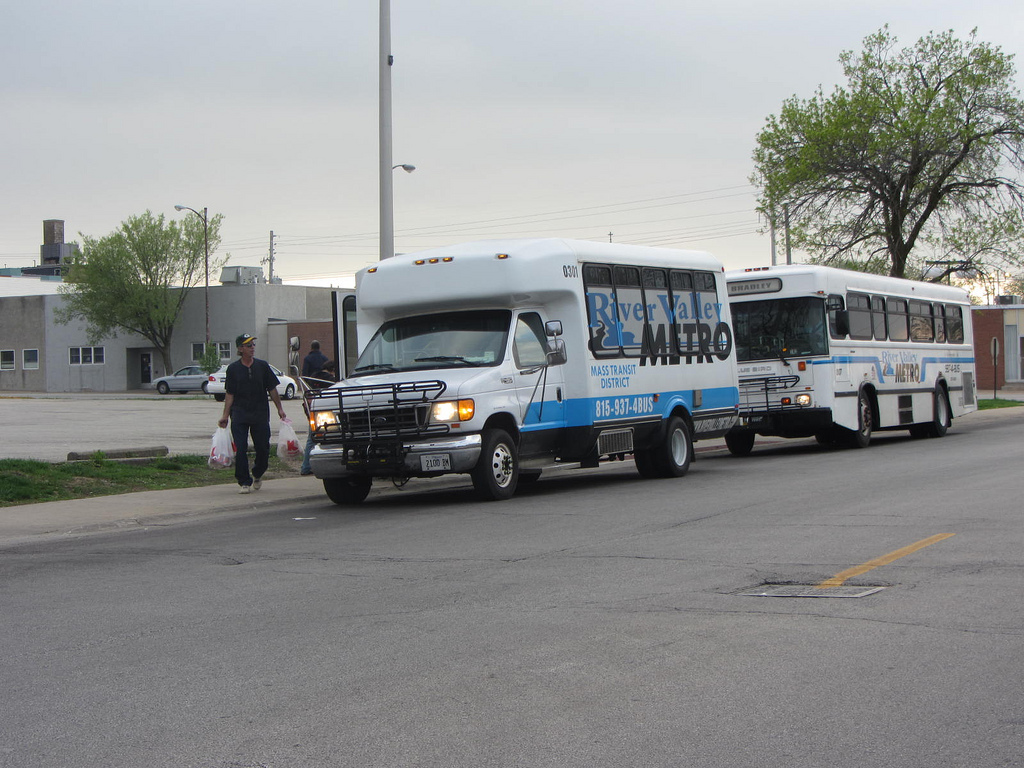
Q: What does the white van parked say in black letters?
A: Metro.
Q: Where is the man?
A: Sidewalk.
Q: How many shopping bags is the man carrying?
A: 2.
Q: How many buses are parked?
A: 2.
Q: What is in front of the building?
A: Tree.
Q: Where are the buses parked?
A: In front of sidewalk.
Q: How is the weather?
A: Overcast.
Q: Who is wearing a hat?
A: Man with bags.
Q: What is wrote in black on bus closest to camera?
A: METRO.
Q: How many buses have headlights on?
A: 2.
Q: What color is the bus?
A: Blue and white.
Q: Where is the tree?
A: Next to the building.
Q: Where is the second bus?
A: Behind the first one.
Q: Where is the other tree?
A: Behind the second bus.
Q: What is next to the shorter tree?
A: A building.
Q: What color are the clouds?
A: White.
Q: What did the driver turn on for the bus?
A: The headlights.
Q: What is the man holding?
A: Grocery bags.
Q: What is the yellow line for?
A: To separate the lanes.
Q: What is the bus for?
A: To carry passengers.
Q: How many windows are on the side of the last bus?
A: Six.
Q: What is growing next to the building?
A: Small tree.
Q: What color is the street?
A: Gray.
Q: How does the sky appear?
A: Overcast.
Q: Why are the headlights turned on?
A: It's overcast.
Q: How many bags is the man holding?
A: Two.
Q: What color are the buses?
A: White and blue.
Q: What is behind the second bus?
A: Tree.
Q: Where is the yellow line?
A: On the street.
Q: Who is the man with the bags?
A: Passenger.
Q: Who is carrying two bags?
A: The man.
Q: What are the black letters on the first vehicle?
A: METRO.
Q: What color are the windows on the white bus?
A: Black.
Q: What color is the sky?
A: Gray.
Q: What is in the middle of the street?
A: Sewer drain.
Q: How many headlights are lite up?
A: Three.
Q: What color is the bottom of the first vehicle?
A: Blue.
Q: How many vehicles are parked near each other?
A: Two.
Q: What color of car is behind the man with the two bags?
A: White.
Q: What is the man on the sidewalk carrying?
A: White bags.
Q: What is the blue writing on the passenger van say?
A: River Valley.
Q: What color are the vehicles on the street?
A: Blue and white.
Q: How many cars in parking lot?
A: Two.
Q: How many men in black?
A: Two.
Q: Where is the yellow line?
A: Center of road.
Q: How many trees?
A: Two.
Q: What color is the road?
A: Gray.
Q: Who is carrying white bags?
A: Man in dark clothes.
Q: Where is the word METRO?
A: Side of first bus.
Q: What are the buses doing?
A: Parked by curb.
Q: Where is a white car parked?
A: Behind man in hat.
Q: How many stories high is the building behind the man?
A: 1.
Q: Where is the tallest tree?
A: Top right.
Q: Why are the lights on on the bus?
A: Getting dark out.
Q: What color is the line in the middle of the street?
A: Yellow.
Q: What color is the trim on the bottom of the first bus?
A: Baby blue.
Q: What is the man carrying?
A: Two bags.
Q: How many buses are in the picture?
A: Two.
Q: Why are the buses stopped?
A: Because passengers are getting off of the buses.